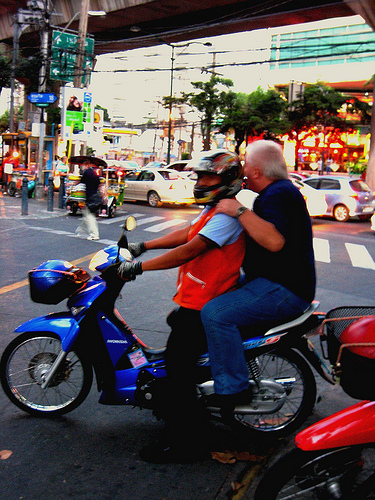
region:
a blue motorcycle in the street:
[0, 215, 336, 436]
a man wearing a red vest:
[116, 152, 247, 463]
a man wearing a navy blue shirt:
[201, 139, 316, 405]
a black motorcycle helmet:
[193, 152, 244, 201]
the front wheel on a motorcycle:
[1, 328, 94, 418]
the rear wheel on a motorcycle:
[221, 341, 316, 442]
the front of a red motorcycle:
[251, 303, 374, 499]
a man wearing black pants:
[117, 152, 246, 460]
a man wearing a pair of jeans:
[202, 140, 318, 405]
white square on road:
[344, 241, 370, 270]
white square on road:
[311, 235, 330, 262]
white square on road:
[143, 217, 186, 230]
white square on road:
[122, 215, 162, 229]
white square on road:
[98, 211, 143, 222]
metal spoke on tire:
[15, 356, 36, 365]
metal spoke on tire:
[12, 381, 35, 390]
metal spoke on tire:
[39, 386, 52, 405]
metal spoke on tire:
[52, 387, 72, 398]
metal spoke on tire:
[278, 358, 284, 377]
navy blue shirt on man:
[243, 179, 316, 307]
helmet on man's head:
[192, 149, 243, 203]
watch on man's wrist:
[231, 204, 247, 219]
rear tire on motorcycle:
[220, 343, 315, 443]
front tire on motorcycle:
[0, 330, 92, 420]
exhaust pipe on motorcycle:
[274, 375, 296, 394]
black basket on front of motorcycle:
[25, 268, 73, 303]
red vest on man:
[170, 205, 246, 310]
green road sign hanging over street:
[47, 28, 95, 83]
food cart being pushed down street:
[61, 154, 125, 214]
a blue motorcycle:
[0, 214, 333, 444]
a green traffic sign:
[49, 28, 95, 84]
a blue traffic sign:
[26, 90, 57, 102]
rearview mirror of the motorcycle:
[120, 211, 139, 230]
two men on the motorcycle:
[117, 136, 319, 466]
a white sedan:
[122, 166, 196, 208]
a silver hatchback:
[300, 174, 373, 224]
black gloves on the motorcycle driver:
[117, 238, 145, 279]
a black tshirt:
[241, 177, 317, 302]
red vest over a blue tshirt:
[173, 198, 245, 309]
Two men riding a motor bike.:
[27, 133, 373, 464]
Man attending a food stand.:
[53, 150, 131, 226]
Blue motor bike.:
[1, 217, 326, 442]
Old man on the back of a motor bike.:
[198, 133, 322, 497]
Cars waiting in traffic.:
[109, 129, 373, 243]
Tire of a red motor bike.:
[237, 393, 368, 495]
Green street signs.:
[39, 15, 111, 96]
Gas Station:
[92, 107, 142, 164]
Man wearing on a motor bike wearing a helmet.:
[120, 144, 247, 468]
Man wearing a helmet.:
[95, 143, 245, 465]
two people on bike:
[117, 116, 341, 302]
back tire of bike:
[219, 338, 328, 446]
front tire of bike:
[1, 325, 106, 419]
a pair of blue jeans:
[200, 276, 309, 394]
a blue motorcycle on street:
[0, 216, 338, 439]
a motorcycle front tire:
[2, 329, 92, 417]